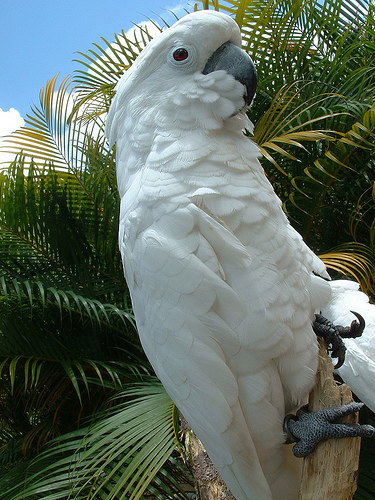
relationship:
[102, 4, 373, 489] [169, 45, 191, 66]
parrot with eye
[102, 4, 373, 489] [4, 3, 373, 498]
parrot near trees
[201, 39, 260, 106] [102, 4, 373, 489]
beak of parrot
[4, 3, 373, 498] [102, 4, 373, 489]
trees near parrot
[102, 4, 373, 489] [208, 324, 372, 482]
parrot on stick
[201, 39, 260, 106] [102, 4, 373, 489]
beak on parrot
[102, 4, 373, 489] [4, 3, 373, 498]
parrot in middle of trees